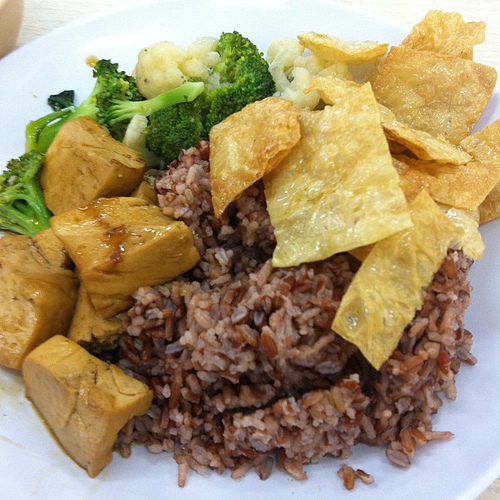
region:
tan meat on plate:
[11, 127, 173, 442]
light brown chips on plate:
[263, 18, 499, 367]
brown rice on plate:
[146, 191, 383, 447]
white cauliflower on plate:
[122, 45, 381, 162]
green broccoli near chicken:
[3, 58, 275, 214]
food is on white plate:
[56, 54, 467, 499]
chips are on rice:
[270, 20, 452, 328]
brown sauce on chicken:
[1, 10, 185, 431]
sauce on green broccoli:
[0, 61, 131, 242]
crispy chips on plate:
[229, 3, 474, 297]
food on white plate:
[5, 9, 490, 499]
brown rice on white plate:
[102, 160, 465, 481]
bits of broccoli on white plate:
[2, 45, 260, 192]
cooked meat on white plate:
[5, 114, 196, 461]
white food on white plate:
[132, 28, 309, 103]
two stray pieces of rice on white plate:
[332, 455, 375, 492]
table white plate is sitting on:
[3, 4, 120, 63]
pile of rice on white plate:
[125, 146, 469, 461]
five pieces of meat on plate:
[2, 123, 182, 444]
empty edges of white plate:
[15, 5, 472, 498]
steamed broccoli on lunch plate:
[205, 32, 260, 97]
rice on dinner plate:
[184, 325, 299, 418]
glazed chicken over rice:
[49, 193, 195, 295]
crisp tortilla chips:
[344, 198, 448, 323]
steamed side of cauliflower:
[110, 35, 208, 80]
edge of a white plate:
[462, 405, 490, 447]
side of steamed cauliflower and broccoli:
[68, 26, 315, 114]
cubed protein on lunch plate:
[47, 195, 197, 305]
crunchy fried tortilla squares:
[371, 38, 486, 158]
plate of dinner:
[8, 60, 498, 288]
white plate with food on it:
[4, 4, 498, 496]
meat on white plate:
[5, 121, 164, 457]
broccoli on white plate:
[5, 40, 262, 220]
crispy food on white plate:
[212, 17, 489, 337]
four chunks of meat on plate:
[9, 115, 209, 460]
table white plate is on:
[4, 4, 66, 48]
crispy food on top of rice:
[195, 93, 449, 375]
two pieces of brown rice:
[338, 463, 372, 491]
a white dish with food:
[3, 2, 497, 498]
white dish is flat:
[3, 0, 499, 499]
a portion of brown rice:
[127, 225, 472, 475]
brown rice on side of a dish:
[132, 231, 488, 498]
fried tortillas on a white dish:
[196, 17, 499, 361]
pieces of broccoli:
[1, 26, 275, 224]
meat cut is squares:
[5, 110, 204, 471]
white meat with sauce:
[6, 111, 206, 476]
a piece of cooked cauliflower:
[132, 18, 224, 98]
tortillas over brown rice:
[185, 84, 452, 421]